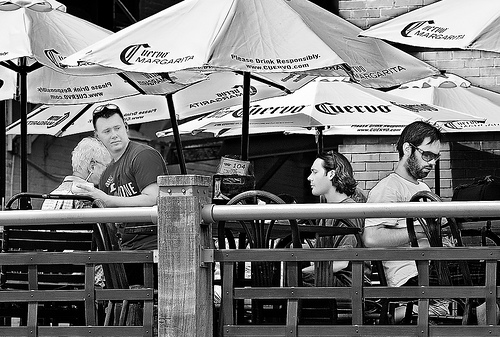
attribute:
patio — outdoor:
[0, 168, 495, 335]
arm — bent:
[82, 180, 158, 206]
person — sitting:
[60, 99, 175, 205]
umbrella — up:
[73, 10, 433, 107]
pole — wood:
[158, 173, 214, 335]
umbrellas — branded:
[62, 5, 437, 122]